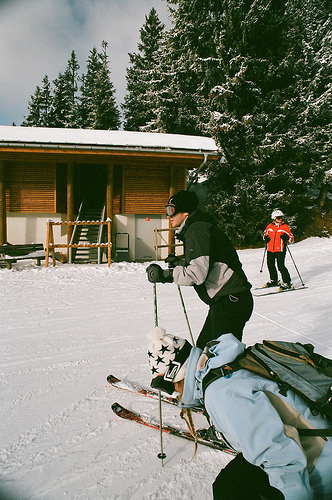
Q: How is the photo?
A: Clear.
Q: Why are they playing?
A: To have fun.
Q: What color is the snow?
A: White.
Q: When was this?
A: Daytime.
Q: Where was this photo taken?
A: At a ski resort.